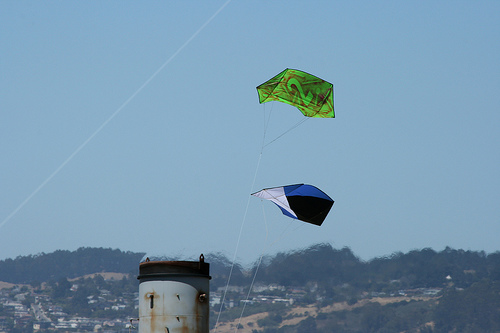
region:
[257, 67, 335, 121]
the green colored kite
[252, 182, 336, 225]
the blue on the kite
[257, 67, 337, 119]
the number 2 on the green kite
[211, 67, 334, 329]
the two kites in the sky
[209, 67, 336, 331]
the strings attached to the kites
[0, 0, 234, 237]
the white kite strings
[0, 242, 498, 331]
the trees near the homes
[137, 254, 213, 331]
the thick pipe with rust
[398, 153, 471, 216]
the sky is clear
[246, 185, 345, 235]
the kite in the air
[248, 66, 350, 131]
a green kite in the sky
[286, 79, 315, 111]
number 2 on the kite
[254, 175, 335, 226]
the kite is black and white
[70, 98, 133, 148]
a line that is white in the sky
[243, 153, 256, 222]
a white string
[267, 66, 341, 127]
green kite in air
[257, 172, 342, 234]
blue and white kite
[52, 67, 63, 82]
white clouds in blue sky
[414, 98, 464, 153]
white clouds in blue sky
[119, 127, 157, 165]
white clouds in blue sky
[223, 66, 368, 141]
green kite in the air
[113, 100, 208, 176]
blue sky above land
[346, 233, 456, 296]
trees in the distance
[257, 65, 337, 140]
a kite that is green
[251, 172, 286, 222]
the white part of a kite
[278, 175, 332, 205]
the blue part of a kite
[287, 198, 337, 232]
the black part of a kite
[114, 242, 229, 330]
a pole that is grey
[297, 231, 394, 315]
some trees on top of a mountain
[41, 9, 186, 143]
a sky that is blue in color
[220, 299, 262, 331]
grass that is brown in color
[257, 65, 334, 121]
kite is in the air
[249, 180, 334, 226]
kite is in the air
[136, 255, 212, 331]
tower is tall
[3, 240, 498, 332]
hill is behind the tower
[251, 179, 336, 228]
kite is blue black and white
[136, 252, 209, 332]
tower is rusting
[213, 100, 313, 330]
string is holding up kite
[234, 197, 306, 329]
string is holding up kite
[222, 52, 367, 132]
green kite in air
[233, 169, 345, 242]
blue, white and black kite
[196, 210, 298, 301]
strings on the kite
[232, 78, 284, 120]
edge of the kite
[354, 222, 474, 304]
trees in the distance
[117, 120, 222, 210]
sky with no clouds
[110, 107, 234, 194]
blue sky above land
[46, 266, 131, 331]
many buildings on ground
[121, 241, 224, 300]
top of the structure